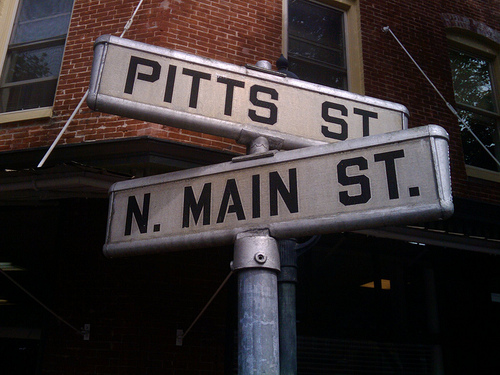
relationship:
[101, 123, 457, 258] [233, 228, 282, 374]
sign on pole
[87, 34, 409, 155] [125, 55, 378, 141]
sign says pitts st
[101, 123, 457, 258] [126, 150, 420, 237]
sign says n. main st.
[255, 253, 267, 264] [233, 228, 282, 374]
bolt on pole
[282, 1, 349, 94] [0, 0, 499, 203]
window on building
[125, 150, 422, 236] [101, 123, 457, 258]
writing on sign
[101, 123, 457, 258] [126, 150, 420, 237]
sign say n. main st.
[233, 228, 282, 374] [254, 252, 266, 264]
pole has hole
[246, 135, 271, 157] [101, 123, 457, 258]
pole behind sign